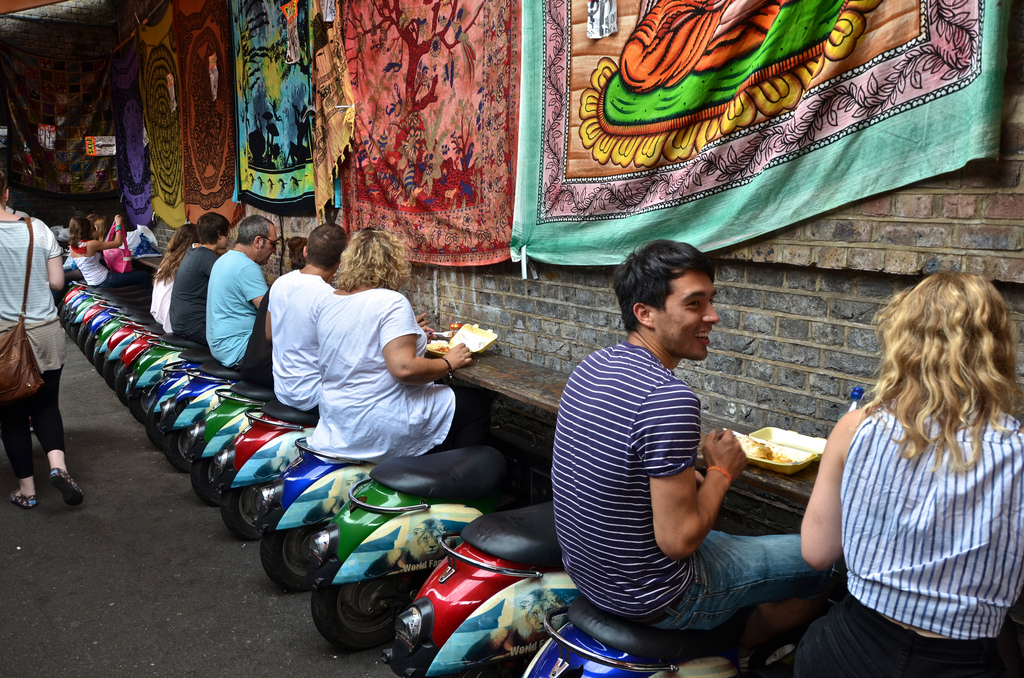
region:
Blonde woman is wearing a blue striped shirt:
[808, 255, 1021, 655]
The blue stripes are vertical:
[849, 394, 1001, 639]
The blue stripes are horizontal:
[531, 315, 708, 642]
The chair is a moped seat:
[286, 405, 525, 658]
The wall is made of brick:
[699, 86, 998, 483]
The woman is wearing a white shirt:
[321, 217, 481, 500]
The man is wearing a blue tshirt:
[185, 206, 342, 369]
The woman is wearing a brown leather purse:
[2, 98, 179, 551]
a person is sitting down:
[548, 238, 836, 635]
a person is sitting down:
[316, 228, 507, 470]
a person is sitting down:
[269, 216, 358, 412]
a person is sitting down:
[197, 219, 289, 390]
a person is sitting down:
[170, 188, 222, 372]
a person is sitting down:
[129, 215, 218, 337]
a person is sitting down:
[124, 213, 137, 245]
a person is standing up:
[6, 177, 83, 516]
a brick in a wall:
[761, 286, 831, 315]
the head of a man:
[588, 217, 728, 376]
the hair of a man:
[610, 236, 696, 301]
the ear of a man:
[623, 296, 662, 335]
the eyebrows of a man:
[680, 292, 723, 297]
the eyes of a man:
[671, 287, 714, 310]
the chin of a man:
[678, 340, 717, 370]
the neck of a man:
[605, 328, 679, 367]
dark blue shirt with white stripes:
[555, 251, 751, 621]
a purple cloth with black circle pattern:
[114, 41, 154, 235]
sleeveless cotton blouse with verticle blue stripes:
[841, 402, 1022, 656]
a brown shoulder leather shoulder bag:
[0, 227, 46, 404]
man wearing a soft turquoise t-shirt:
[199, 246, 260, 368]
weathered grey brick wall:
[400, 190, 1023, 441]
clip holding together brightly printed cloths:
[508, 243, 546, 288]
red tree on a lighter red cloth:
[351, 6, 476, 168]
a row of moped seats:
[202, 388, 680, 673]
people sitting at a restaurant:
[123, 196, 509, 573]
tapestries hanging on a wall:
[44, 0, 987, 280]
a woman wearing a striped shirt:
[824, 202, 1020, 665]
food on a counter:
[710, 410, 848, 505]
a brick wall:
[721, 252, 868, 452]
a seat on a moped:
[358, 429, 514, 515]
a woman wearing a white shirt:
[312, 216, 483, 464]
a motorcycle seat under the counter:
[484, 449, 583, 589]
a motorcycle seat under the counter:
[572, 553, 686, 675]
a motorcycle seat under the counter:
[259, 400, 457, 537]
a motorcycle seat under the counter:
[107, 369, 197, 445]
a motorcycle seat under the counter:
[204, 405, 285, 491]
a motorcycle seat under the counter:
[283, 445, 313, 540]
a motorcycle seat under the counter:
[68, 281, 116, 326]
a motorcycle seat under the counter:
[128, 316, 145, 364]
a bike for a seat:
[430, 434, 544, 603]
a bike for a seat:
[567, 560, 675, 671]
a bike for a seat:
[450, 508, 569, 665]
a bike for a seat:
[342, 423, 459, 572]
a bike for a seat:
[251, 487, 411, 595]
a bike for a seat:
[216, 396, 344, 501]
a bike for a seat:
[169, 338, 253, 443]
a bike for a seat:
[163, 332, 195, 416]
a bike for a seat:
[93, 271, 163, 361]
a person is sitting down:
[796, 267, 1012, 670]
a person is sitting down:
[549, 228, 835, 674]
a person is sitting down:
[309, 231, 521, 450]